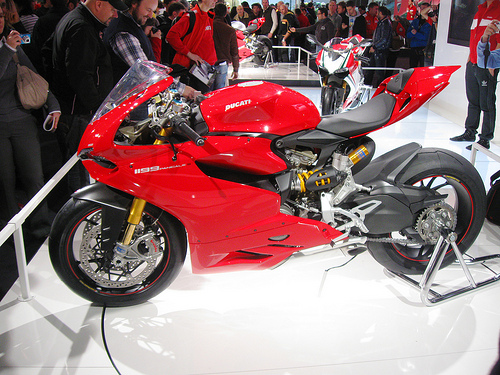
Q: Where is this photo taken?
A: A convention.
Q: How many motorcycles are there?
A: Three.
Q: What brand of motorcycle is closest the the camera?
A: Ducati.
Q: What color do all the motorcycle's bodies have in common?
A: Red.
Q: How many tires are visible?
A: Four.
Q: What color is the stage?
A: White.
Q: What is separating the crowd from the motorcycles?
A: Railing.